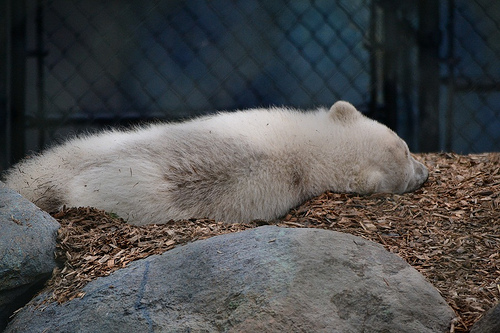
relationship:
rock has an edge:
[1, 219, 471, 333] [107, 219, 420, 265]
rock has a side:
[1, 219, 471, 333] [107, 219, 420, 265]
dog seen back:
[5, 89, 433, 233] [31, 121, 382, 190]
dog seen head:
[5, 89, 433, 233] [317, 92, 436, 206]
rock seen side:
[1, 219, 471, 333] [107, 219, 420, 265]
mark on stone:
[105, 262, 178, 320] [1, 219, 471, 333]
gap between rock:
[53, 228, 103, 278] [0, 225, 456, 333]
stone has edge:
[1, 219, 471, 333] [107, 219, 420, 265]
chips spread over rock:
[49, 223, 180, 307] [0, 225, 456, 333]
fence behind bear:
[1, 2, 496, 101] [5, 89, 433, 233]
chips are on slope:
[49, 223, 180, 307] [1, 219, 471, 333]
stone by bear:
[1, 219, 471, 333] [5, 89, 433, 233]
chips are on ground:
[365, 195, 500, 268] [335, 186, 499, 269]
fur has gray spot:
[5, 89, 433, 233] [155, 132, 282, 218]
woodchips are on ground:
[365, 195, 500, 268] [335, 186, 499, 269]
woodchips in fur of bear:
[45, 192, 126, 241] [5, 89, 433, 233]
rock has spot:
[1, 219, 471, 333] [329, 283, 399, 333]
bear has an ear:
[5, 89, 433, 233] [362, 164, 390, 200]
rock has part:
[1, 219, 471, 333] [215, 279, 238, 308]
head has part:
[317, 92, 436, 206] [366, 155, 387, 176]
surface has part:
[335, 186, 499, 269] [432, 194, 446, 224]